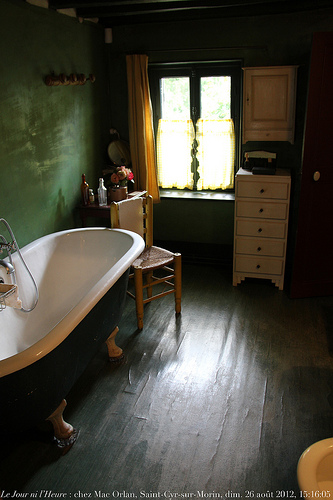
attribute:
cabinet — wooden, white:
[234, 64, 298, 145]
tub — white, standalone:
[0, 226, 144, 451]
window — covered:
[146, 65, 238, 190]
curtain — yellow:
[117, 70, 163, 212]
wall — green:
[0, 0, 115, 259]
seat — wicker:
[129, 242, 175, 270]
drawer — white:
[220, 160, 298, 295]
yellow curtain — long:
[121, 48, 163, 203]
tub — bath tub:
[0, 167, 192, 476]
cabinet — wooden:
[206, 178, 298, 312]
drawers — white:
[234, 179, 289, 277]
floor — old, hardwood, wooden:
[0, 259, 332, 499]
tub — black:
[0, 259, 117, 344]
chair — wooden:
[112, 193, 182, 329]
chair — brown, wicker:
[107, 192, 185, 330]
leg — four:
[171, 252, 181, 314]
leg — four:
[132, 264, 144, 330]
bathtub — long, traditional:
[0, 223, 168, 434]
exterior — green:
[10, 44, 102, 213]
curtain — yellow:
[154, 116, 195, 189]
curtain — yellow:
[194, 115, 237, 190]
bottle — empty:
[95, 174, 108, 207]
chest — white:
[227, 162, 294, 290]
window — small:
[145, 59, 240, 198]